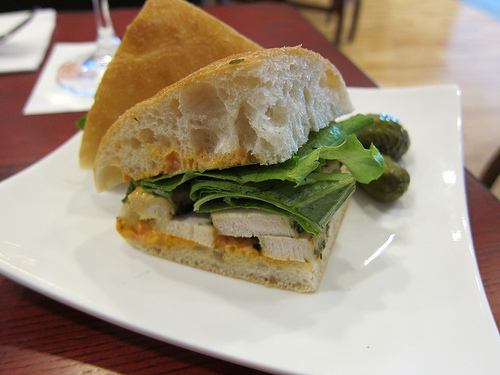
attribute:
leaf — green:
[146, 171, 353, 212]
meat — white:
[233, 210, 301, 257]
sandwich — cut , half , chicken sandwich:
[71, 5, 408, 295]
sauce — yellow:
[118, 212, 195, 249]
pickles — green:
[332, 109, 409, 206]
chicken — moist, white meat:
[216, 210, 321, 260]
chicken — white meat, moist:
[161, 210, 218, 249]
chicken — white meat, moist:
[117, 189, 170, 230]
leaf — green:
[288, 159, 364, 210]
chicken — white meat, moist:
[128, 187, 332, 262]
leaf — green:
[284, 128, 395, 238]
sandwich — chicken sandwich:
[77, 0, 360, 294]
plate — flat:
[86, 41, 488, 373]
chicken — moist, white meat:
[161, 212, 215, 246]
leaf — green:
[191, 172, 346, 209]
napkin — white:
[43, 44, 103, 124]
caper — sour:
[367, 111, 412, 156]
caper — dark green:
[354, 151, 412, 213]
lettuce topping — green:
[133, 111, 385, 237]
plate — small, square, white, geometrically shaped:
[0, 82, 499, 373]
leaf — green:
[120, 110, 386, 231]